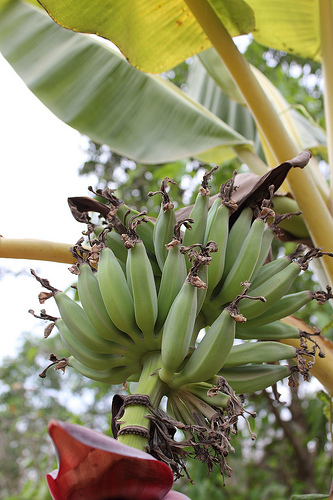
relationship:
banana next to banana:
[54, 195, 311, 396] [126, 239, 157, 335]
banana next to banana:
[54, 195, 311, 396] [54, 195, 311, 396]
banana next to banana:
[54, 195, 311, 396] [225, 340, 298, 370]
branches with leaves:
[192, 29, 331, 183] [52, 7, 277, 167]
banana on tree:
[54, 195, 311, 396] [0, 1, 332, 291]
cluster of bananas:
[30, 241, 315, 403] [43, 172, 325, 397]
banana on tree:
[54, 195, 311, 396] [0, 1, 330, 497]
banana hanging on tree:
[54, 195, 311, 396] [7, 126, 322, 483]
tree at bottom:
[0, 1, 330, 497] [87, 417, 173, 498]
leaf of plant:
[42, 417, 174, 498] [42, 173, 291, 458]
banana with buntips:
[54, 195, 311, 396] [82, 151, 325, 287]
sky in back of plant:
[11, 123, 90, 352] [0, 329, 332, 497]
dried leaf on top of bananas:
[144, 147, 313, 223] [37, 186, 332, 455]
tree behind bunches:
[0, 0, 333, 500] [54, 191, 328, 467]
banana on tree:
[54, 195, 311, 396] [58, 0, 332, 401]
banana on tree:
[169, 273, 210, 366] [66, 250, 268, 398]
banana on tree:
[54, 195, 311, 396] [8, 0, 321, 171]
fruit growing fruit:
[169, 296, 241, 396] [148, 251, 215, 378]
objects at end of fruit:
[199, 168, 229, 197] [164, 158, 304, 246]